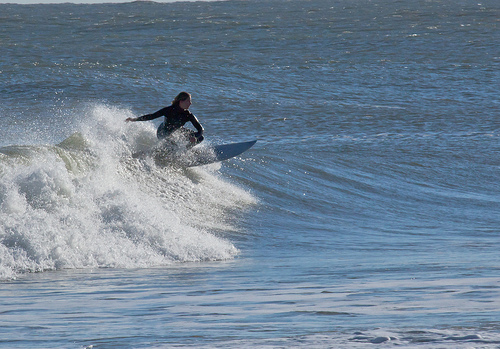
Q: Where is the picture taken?
A: The ocean.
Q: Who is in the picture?
A: A woman.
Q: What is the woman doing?
A: Surfing.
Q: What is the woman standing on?
A: A surfboard.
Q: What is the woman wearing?
A: Wetsuit.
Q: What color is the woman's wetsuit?
A: Black.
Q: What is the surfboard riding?
A: A wave.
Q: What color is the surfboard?
A: White.